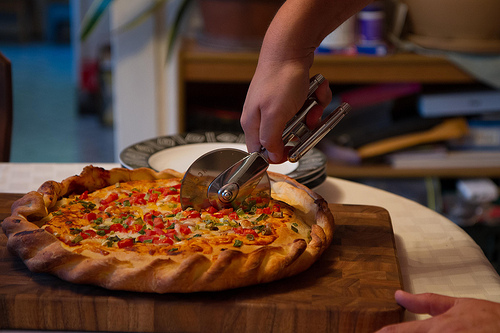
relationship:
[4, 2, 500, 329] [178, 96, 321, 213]
scene shows pizza cutter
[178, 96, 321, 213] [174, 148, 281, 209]
pizza cutter has a blade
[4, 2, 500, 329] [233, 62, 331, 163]
scene shows hand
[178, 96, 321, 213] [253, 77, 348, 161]
pizza cutter has handle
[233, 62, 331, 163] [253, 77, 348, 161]
hand grips handle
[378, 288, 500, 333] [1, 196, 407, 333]
left hand holding cutting board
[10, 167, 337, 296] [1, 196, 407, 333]
pizza on top of cutting board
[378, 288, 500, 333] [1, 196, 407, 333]
left hand has corner of wooden cutting board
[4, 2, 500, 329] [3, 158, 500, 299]
scene has a table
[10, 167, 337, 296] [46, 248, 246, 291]
pizza has a crust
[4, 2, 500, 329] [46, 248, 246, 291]
scene shows twisted pizza crust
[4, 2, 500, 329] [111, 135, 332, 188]
scene shows stack of plates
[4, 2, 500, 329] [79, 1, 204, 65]
scene shows leaves of a plant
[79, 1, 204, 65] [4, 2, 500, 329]
leaves of a plant hang down in scene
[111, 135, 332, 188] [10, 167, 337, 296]
stack of plates beside pizza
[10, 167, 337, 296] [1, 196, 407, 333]
pizza atop of wooden cutting board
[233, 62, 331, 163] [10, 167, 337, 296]
hand of person cutting pizza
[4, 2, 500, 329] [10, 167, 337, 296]
scene has blurry hall past pizza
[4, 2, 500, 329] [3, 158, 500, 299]
scene shows white cloth on table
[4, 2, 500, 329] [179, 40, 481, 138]
scene shows messy desk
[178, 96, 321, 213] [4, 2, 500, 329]
pizza cutter part of scene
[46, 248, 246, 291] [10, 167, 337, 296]
crust on pizza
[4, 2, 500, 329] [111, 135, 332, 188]
scene shows a plate on stack of plates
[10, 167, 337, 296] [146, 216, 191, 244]
pizza has red peppers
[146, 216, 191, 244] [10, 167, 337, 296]
red peppers are on top of pizza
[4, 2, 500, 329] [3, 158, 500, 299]
scene shows table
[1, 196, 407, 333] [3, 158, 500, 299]
cutting board on top of table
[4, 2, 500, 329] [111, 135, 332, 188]
scene shows  plates in a stack of plates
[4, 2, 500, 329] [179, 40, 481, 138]
scene includes books in a desk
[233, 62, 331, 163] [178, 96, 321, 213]
hand of person using pizza cutter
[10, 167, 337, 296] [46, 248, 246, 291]
pizza has a breaded crust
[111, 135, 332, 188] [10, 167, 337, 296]
stack of plates are in back of pizza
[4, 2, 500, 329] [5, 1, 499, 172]
scene shows background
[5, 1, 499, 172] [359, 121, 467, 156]
background shows cooking utensil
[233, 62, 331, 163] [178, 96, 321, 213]
hand of person holding pizza cutter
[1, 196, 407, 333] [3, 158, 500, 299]
cutting board sitting upon table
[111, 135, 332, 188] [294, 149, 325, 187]
stack of plates show a dark rim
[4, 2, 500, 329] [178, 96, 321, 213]
scene shows a pizza cutter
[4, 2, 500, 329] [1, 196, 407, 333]
scene has brown cutting board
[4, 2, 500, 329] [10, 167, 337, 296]
scene has a pizza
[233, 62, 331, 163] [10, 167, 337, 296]
hand of person cutting piece of pizza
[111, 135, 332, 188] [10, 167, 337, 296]
stack of plates are for serving pizza